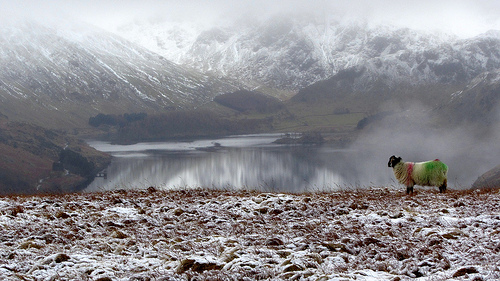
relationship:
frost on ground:
[0, 189, 499, 280] [1, 187, 499, 279]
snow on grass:
[0, 189, 499, 280] [1, 200, 499, 269]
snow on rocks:
[0, 189, 499, 280] [175, 209, 451, 279]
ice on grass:
[0, 189, 499, 280] [24, 191, 442, 274]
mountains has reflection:
[137, 11, 380, 121] [113, 152, 328, 189]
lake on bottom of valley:
[82, 131, 391, 198] [34, 94, 488, 204]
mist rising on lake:
[1, 4, 496, 63] [82, 131, 391, 198]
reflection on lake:
[113, 152, 328, 189] [82, 131, 391, 198]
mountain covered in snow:
[4, 3, 499, 118] [4, 3, 496, 99]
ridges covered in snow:
[0, 34, 296, 90] [4, 3, 496, 99]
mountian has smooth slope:
[4, 3, 499, 118] [103, 48, 358, 100]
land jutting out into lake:
[68, 100, 393, 196] [82, 131, 391, 198]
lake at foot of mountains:
[82, 131, 391, 198] [4, 3, 499, 118]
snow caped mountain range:
[4, 3, 496, 99] [4, 3, 499, 118]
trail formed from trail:
[78, 119, 129, 155] [78, 119, 129, 155]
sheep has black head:
[382, 147, 455, 200] [384, 151, 405, 170]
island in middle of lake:
[196, 137, 234, 154] [82, 131, 391, 198]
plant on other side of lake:
[215, 86, 289, 116] [82, 131, 391, 198]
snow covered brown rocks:
[0, 189, 499, 280] [35, 203, 442, 268]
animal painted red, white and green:
[382, 147, 455, 200] [402, 158, 448, 187]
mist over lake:
[1, 4, 496, 63] [82, 131, 391, 198]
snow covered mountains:
[4, 3, 496, 99] [4, 3, 499, 118]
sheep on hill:
[382, 147, 455, 200] [0, 189, 499, 280]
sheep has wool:
[382, 147, 455, 200] [402, 158, 448, 187]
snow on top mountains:
[4, 3, 496, 99] [4, 3, 499, 118]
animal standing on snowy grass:
[382, 147, 455, 200] [0, 189, 499, 280]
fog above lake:
[1, 4, 496, 63] [82, 131, 391, 198]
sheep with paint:
[382, 147, 455, 200] [402, 158, 448, 187]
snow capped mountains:
[4, 3, 496, 99] [4, 3, 499, 118]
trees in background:
[215, 86, 289, 116] [4, 3, 499, 118]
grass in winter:
[4, 185, 487, 203] [2, 4, 498, 280]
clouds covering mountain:
[3, 2, 495, 38] [4, 3, 499, 118]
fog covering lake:
[46, 84, 477, 187] [82, 131, 391, 198]